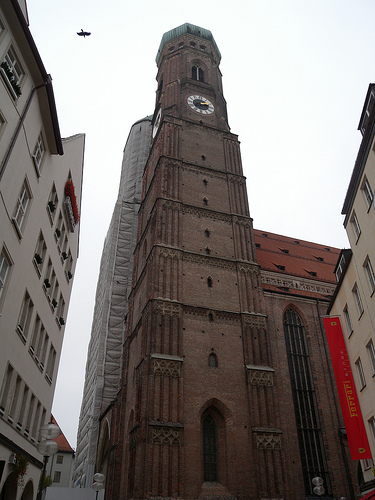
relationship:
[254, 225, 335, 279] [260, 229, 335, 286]
home with roof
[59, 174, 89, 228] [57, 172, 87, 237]
flowers ar on window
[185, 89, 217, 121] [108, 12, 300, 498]
clock on front of church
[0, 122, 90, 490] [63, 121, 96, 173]
building has pointy top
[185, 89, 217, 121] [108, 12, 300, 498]
clock on top of church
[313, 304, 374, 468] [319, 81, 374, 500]
flag hanging from building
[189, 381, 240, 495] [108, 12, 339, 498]
fanc carvings on church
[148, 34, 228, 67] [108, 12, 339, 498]
fence on top of church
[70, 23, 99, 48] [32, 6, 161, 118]
bird flying in air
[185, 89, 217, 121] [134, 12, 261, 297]
clock on top of tower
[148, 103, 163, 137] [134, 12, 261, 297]
clock on side of tower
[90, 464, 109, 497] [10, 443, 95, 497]
lights on left side of street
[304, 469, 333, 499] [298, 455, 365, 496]
lights on right side of street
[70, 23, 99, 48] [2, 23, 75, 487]
bird over buildings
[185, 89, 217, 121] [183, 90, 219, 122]
clock displays roman numerals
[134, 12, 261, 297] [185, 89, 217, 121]
tower has clock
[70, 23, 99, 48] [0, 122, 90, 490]
bird flying over building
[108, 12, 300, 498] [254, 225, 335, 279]
church has red roof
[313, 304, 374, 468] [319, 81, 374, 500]
letters on front of building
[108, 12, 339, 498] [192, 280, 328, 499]
building has arch windows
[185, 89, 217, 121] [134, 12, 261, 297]
clock on tower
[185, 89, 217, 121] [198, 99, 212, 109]
clock has gold hand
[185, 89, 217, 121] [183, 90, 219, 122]
clock has roman numerals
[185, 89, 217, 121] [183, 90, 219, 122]
circle has roman numerals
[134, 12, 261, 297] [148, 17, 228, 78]
tower has octagonal top